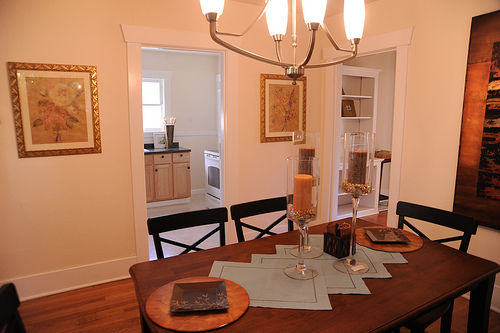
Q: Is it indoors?
A: Yes, it is indoors.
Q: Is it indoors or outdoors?
A: It is indoors.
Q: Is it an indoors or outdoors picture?
A: It is indoors.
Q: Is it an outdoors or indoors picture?
A: It is indoors.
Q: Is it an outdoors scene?
A: No, it is indoors.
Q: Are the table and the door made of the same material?
A: Yes, both the table and the door are made of wood.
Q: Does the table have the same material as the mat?
A: Yes, both the table and the mat are made of wood.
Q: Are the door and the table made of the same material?
A: Yes, both the door and the table are made of wood.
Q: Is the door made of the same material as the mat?
A: Yes, both the door and the mat are made of wood.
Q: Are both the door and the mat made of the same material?
A: Yes, both the door and the mat are made of wood.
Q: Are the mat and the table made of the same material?
A: Yes, both the mat and the table are made of wood.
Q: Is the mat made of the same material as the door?
A: Yes, both the mat and the door are made of wood.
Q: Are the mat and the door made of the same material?
A: Yes, both the mat and the door are made of wood.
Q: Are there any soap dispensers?
A: No, there are no soap dispensers.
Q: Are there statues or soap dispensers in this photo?
A: No, there are no soap dispensers or statues.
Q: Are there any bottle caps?
A: No, there are no bottle caps.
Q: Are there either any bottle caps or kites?
A: No, there are no bottle caps or kites.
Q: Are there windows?
A: Yes, there is a window.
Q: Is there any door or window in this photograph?
A: Yes, there is a window.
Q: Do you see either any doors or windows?
A: Yes, there is a window.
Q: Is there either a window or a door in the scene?
A: Yes, there is a window.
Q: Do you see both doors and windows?
A: Yes, there are both a window and a door.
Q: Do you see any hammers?
A: No, there are no hammers.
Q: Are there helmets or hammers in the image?
A: No, there are no hammers or helmets.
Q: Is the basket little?
A: Yes, the basket is little.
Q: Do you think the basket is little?
A: Yes, the basket is little.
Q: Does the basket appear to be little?
A: Yes, the basket is little.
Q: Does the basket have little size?
A: Yes, the basket is little.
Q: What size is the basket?
A: The basket is little.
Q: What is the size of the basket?
A: The basket is little.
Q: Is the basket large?
A: No, the basket is little.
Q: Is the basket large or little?
A: The basket is little.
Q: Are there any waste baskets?
A: No, there are no waste baskets.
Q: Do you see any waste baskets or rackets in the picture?
A: No, there are no waste baskets or rackets.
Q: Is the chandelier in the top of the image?
A: Yes, the chandelier is in the top of the image.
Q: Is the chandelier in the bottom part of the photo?
A: No, the chandelier is in the top of the image.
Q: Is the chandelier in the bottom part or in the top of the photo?
A: The chandelier is in the top of the image.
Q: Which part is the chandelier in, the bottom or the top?
A: The chandelier is in the top of the image.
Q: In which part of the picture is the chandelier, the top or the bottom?
A: The chandelier is in the top of the image.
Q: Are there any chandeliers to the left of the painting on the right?
A: Yes, there is a chandelier to the left of the painting.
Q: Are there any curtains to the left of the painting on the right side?
A: No, there is a chandelier to the left of the painting.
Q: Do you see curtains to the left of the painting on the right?
A: No, there is a chandelier to the left of the painting.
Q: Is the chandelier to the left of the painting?
A: Yes, the chandelier is to the left of the painting.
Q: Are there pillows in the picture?
A: No, there are no pillows.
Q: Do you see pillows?
A: No, there are no pillows.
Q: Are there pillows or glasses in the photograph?
A: No, there are no pillows or glasses.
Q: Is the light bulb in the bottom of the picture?
A: No, the light bulb is in the top of the image.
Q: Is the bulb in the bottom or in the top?
A: The bulb is in the top of the image.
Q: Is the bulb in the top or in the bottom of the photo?
A: The bulb is in the top of the image.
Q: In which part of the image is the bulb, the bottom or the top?
A: The bulb is in the top of the image.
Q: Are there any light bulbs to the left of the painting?
A: Yes, there is a light bulb to the left of the painting.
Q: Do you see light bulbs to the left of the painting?
A: Yes, there is a light bulb to the left of the painting.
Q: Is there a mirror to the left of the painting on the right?
A: No, there is a light bulb to the left of the painting.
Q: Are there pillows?
A: No, there are no pillows.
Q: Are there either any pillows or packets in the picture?
A: No, there are no pillows or packets.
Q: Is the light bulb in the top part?
A: Yes, the light bulb is in the top of the image.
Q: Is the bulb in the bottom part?
A: No, the bulb is in the top of the image.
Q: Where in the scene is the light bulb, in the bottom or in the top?
A: The light bulb is in the top of the image.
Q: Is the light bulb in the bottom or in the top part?
A: The light bulb is in the top of the image.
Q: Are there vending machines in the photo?
A: No, there are no vending machines.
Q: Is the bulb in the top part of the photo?
A: Yes, the bulb is in the top of the image.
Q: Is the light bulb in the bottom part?
A: No, the light bulb is in the top of the image.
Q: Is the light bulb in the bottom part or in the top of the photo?
A: The light bulb is in the top of the image.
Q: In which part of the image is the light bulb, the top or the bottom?
A: The light bulb is in the top of the image.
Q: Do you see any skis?
A: No, there are no skis.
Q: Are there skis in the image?
A: No, there are no skis.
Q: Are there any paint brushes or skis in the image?
A: No, there are no skis or paint brushes.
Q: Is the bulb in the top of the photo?
A: Yes, the bulb is in the top of the image.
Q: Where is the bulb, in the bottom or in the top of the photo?
A: The bulb is in the top of the image.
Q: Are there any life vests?
A: No, there are no life vests.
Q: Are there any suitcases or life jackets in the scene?
A: No, there are no life jackets or suitcases.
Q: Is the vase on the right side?
A: Yes, the vase is on the right of the image.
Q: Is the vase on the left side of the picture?
A: No, the vase is on the right of the image.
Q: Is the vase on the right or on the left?
A: The vase is on the right of the image.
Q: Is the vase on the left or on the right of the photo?
A: The vase is on the right of the image.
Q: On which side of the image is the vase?
A: The vase is on the right of the image.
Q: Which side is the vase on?
A: The vase is on the right of the image.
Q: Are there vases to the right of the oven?
A: Yes, there is a vase to the right of the oven.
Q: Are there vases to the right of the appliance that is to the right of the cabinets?
A: Yes, there is a vase to the right of the oven.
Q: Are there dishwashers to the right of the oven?
A: No, there is a vase to the right of the oven.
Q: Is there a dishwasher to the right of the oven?
A: No, there is a vase to the right of the oven.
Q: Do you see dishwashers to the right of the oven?
A: No, there is a vase to the right of the oven.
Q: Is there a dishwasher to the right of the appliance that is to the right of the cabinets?
A: No, there is a vase to the right of the oven.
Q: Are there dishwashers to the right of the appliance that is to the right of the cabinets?
A: No, there is a vase to the right of the oven.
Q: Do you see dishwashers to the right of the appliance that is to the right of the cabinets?
A: No, there is a vase to the right of the oven.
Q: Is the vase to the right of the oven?
A: Yes, the vase is to the right of the oven.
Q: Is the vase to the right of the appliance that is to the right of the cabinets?
A: Yes, the vase is to the right of the oven.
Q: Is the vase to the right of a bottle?
A: No, the vase is to the right of the oven.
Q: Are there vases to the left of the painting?
A: Yes, there is a vase to the left of the painting.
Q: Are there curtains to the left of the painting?
A: No, there is a vase to the left of the painting.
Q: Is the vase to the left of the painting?
A: Yes, the vase is to the left of the painting.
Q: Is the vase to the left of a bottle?
A: No, the vase is to the left of the painting.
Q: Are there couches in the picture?
A: No, there are no couches.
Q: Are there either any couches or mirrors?
A: No, there are no couches or mirrors.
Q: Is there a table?
A: Yes, there is a table.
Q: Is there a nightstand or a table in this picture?
A: Yes, there is a table.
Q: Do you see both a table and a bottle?
A: No, there is a table but no bottles.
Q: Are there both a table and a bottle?
A: No, there is a table but no bottles.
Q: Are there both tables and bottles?
A: No, there is a table but no bottles.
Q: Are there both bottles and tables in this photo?
A: No, there is a table but no bottles.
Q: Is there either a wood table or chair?
A: Yes, there is a wood table.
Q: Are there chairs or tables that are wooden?
A: Yes, the table is wooden.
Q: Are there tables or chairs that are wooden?
A: Yes, the table is wooden.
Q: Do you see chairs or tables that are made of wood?
A: Yes, the table is made of wood.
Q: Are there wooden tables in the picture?
A: Yes, there is a wood table.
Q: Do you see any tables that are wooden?
A: Yes, there is a table that is wooden.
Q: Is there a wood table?
A: Yes, there is a table that is made of wood.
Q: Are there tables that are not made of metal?
A: Yes, there is a table that is made of wood.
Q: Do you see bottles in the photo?
A: No, there are no bottles.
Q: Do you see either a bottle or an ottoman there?
A: No, there are no bottles or ottomen.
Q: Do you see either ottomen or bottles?
A: No, there are no bottles or ottomen.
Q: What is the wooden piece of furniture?
A: The piece of furniture is a table.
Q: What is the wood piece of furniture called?
A: The piece of furniture is a table.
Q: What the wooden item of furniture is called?
A: The piece of furniture is a table.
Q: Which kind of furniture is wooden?
A: The furniture is a table.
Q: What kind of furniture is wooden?
A: The furniture is a table.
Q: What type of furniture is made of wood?
A: The furniture is a table.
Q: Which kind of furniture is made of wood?
A: The furniture is a table.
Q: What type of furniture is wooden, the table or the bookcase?
A: The table is wooden.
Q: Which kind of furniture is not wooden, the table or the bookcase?
A: The bookcase is not wooden.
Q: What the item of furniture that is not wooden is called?
A: The piece of furniture is a bookcase.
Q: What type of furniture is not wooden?
A: The furniture is a bookcase.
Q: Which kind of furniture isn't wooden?
A: The furniture is a bookcase.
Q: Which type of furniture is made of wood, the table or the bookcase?
A: The table is made of wood.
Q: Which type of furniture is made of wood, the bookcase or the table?
A: The table is made of wood.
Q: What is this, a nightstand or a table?
A: This is a table.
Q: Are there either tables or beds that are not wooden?
A: No, there is a table but it is wooden.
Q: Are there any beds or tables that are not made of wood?
A: No, there is a table but it is made of wood.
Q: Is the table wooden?
A: Yes, the table is wooden.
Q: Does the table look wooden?
A: Yes, the table is wooden.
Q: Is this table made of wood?
A: Yes, the table is made of wood.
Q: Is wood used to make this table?
A: Yes, the table is made of wood.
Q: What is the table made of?
A: The table is made of wood.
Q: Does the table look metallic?
A: No, the table is wooden.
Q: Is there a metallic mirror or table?
A: No, there is a table but it is wooden.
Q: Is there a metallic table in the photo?
A: No, there is a table but it is wooden.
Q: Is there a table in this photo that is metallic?
A: No, there is a table but it is wooden.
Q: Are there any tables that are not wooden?
A: No, there is a table but it is wooden.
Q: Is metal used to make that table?
A: No, the table is made of wood.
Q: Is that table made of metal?
A: No, the table is made of wood.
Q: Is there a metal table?
A: No, there is a table but it is made of wood.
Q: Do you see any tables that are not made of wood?
A: No, there is a table but it is made of wood.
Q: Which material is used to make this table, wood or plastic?
A: The table is made of wood.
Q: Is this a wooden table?
A: Yes, this is a wooden table.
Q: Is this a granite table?
A: No, this is a wooden table.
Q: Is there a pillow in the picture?
A: No, there are no pillows.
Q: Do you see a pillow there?
A: No, there are no pillows.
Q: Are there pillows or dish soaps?
A: No, there are no pillows or dish soaps.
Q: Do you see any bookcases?
A: Yes, there is a bookcase.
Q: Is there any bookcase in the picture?
A: Yes, there is a bookcase.